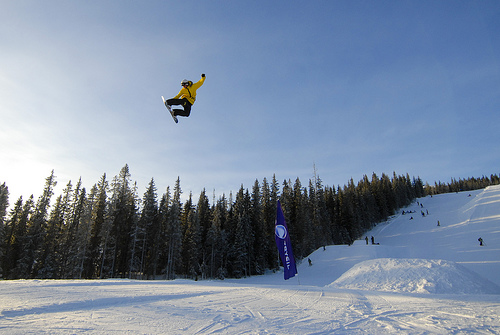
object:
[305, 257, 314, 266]
people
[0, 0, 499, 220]
sky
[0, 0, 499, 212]
clouds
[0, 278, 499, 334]
snow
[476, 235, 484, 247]
people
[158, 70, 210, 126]
going up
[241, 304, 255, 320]
line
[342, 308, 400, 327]
line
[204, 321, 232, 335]
line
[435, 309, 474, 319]
line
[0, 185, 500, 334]
snow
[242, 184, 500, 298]
slope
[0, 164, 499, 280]
tree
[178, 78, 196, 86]
helmet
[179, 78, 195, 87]
head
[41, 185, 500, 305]
shadows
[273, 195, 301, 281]
flag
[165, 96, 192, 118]
pants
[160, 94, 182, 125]
snowboard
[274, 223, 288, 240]
sign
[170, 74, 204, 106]
jacket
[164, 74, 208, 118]
boy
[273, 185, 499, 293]
hill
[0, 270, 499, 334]
ground